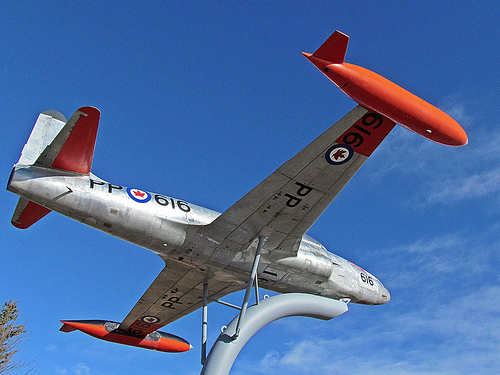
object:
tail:
[4, 104, 104, 230]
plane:
[0, 29, 486, 359]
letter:
[295, 181, 314, 197]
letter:
[284, 193, 303, 209]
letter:
[167, 296, 185, 305]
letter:
[161, 300, 176, 310]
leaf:
[5, 307, 12, 311]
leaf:
[10, 331, 14, 337]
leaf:
[4, 342, 8, 347]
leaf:
[0, 333, 4, 340]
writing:
[89, 178, 192, 213]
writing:
[323, 143, 354, 166]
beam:
[262, 293, 347, 317]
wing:
[217, 109, 408, 234]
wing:
[109, 264, 242, 332]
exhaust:
[6, 167, 16, 190]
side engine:
[295, 29, 471, 152]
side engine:
[55, 313, 196, 360]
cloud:
[407, 315, 499, 374]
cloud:
[440, 179, 493, 199]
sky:
[0, 0, 498, 374]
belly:
[97, 202, 170, 253]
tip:
[386, 296, 392, 303]